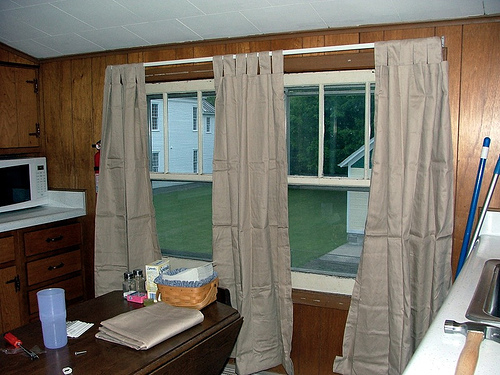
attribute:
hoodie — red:
[95, 282, 217, 369]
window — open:
[144, 86, 217, 257]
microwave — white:
[1, 155, 48, 219]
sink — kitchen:
[466, 258, 499, 322]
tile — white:
[54, 5, 108, 39]